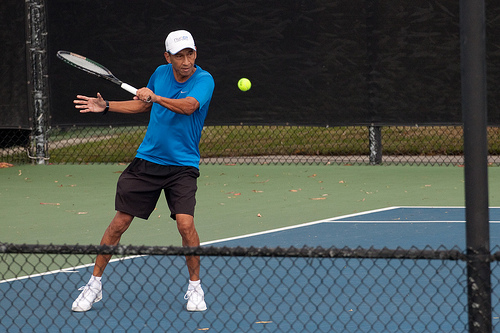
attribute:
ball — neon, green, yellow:
[233, 73, 255, 95]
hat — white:
[158, 27, 201, 58]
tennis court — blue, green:
[3, 164, 499, 333]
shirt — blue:
[132, 63, 216, 172]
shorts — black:
[114, 157, 203, 221]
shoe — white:
[182, 278, 211, 314]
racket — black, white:
[54, 45, 140, 102]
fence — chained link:
[2, 237, 499, 329]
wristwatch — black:
[103, 98, 112, 114]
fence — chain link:
[1, 1, 500, 168]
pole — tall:
[455, 2, 496, 333]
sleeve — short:
[187, 70, 218, 116]